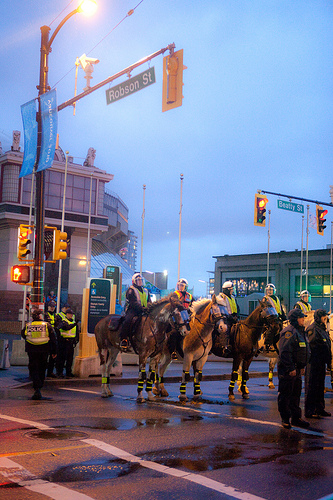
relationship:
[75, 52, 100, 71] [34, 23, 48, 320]
camera on pole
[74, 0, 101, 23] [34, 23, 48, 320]
light on pole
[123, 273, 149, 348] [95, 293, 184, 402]
policeman on horse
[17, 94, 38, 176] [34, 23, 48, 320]
banner on pole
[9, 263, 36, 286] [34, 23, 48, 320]
pedestrian sign on pole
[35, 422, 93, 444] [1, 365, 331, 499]
manhole on street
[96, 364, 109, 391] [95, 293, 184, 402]
sock on horse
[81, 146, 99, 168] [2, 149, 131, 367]
gargoyle on building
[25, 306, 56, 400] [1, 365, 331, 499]
cop on street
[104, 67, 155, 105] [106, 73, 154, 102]
sign has lettering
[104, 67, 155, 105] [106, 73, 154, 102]
sign with lettering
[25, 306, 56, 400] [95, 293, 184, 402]
cop by horse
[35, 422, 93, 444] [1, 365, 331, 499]
manhole in street